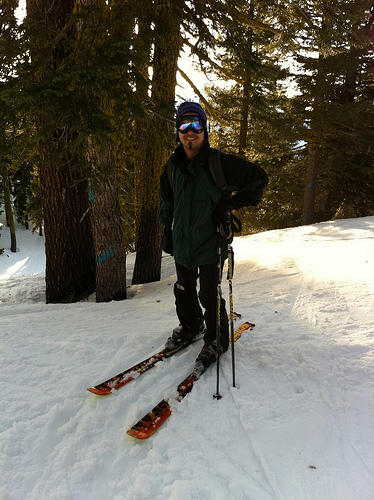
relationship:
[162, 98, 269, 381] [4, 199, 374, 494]
skier in mountains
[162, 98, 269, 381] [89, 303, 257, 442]
skier has skis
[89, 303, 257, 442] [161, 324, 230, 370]
skis on feet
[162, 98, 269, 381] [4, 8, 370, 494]
skier enjoying outdoors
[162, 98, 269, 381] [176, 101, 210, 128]
skier wearing hat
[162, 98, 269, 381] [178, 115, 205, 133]
skier wearing goggles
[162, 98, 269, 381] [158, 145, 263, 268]
skier wearing jacket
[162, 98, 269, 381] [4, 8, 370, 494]
skier close to trees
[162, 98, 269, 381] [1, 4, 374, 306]
skier standing close to trees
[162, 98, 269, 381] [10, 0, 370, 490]
skier planning fun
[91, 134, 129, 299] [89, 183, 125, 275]
tree has mark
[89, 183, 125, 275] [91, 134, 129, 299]
mark on tree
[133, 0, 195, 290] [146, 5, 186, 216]
tree has moss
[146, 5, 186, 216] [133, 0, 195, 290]
moss on tree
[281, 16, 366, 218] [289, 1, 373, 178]
tree has pine needles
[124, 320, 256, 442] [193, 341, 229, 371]
skis on foot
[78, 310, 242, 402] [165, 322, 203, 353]
ski on foot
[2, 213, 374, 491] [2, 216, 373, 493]
snow covers ground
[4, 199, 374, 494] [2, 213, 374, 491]
tracks throughout snow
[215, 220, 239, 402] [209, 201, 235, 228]
ski poles in hand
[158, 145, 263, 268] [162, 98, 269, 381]
jacket on skier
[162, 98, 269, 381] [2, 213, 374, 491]
skier in snow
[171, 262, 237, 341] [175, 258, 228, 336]
pants on legs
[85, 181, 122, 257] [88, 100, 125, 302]
spray paint on tree trunk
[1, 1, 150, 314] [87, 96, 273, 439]
tree behind skier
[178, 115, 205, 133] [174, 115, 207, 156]
goggles on face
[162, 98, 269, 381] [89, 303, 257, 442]
skier standing on skis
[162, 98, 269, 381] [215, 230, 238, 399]
skier holding ski sticks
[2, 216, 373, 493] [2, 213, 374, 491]
ground covered in snow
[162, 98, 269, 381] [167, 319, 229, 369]
skier wearing snow boots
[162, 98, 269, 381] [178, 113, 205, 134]
skier wearing sunglasses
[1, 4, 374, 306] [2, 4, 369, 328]
trees in background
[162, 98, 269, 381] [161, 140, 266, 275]
skier wearing snow jacket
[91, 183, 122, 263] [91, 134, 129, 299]
paint on tree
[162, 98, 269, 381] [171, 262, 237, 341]
skier wearing pants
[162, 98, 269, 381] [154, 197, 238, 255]
skier wearing gloves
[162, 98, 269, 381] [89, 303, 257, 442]
skier wearing skis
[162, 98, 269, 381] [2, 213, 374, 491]
skier standing on snow